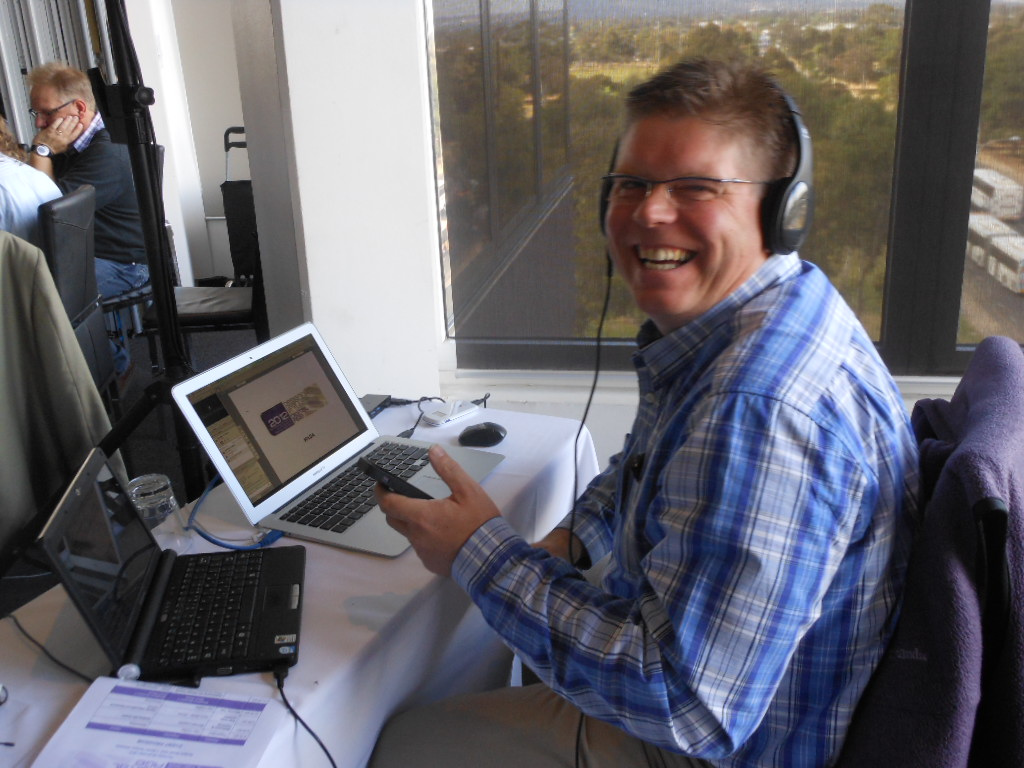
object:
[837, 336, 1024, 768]
jacket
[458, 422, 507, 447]
mouse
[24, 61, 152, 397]
man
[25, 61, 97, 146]
head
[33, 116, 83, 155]
hand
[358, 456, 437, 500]
device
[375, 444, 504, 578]
man's hand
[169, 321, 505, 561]
laptop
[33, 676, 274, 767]
booklet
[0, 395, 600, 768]
table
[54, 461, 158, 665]
screen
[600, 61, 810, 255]
headset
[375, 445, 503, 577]
hand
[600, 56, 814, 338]
headphones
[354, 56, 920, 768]
man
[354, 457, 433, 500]
phone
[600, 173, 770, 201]
glasses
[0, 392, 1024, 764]
furniture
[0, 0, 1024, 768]
building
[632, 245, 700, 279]
smile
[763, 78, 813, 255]
headset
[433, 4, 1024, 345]
trees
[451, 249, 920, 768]
shirt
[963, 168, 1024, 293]
cars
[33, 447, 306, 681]
laptop